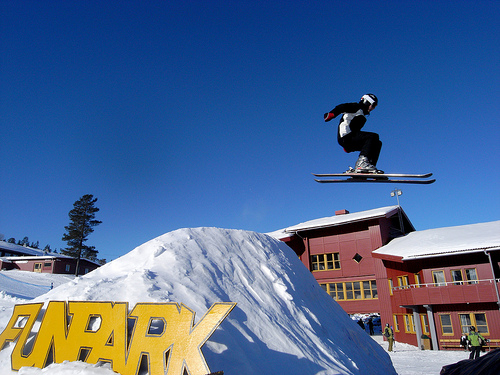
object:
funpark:
[0, 298, 240, 375]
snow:
[185, 238, 244, 287]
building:
[260, 186, 499, 353]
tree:
[59, 195, 104, 276]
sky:
[93, 4, 245, 119]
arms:
[330, 103, 360, 119]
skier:
[323, 90, 386, 177]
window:
[309, 251, 341, 272]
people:
[465, 327, 490, 360]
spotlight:
[388, 191, 397, 199]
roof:
[370, 219, 500, 264]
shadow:
[201, 260, 325, 375]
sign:
[0, 300, 237, 375]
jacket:
[467, 330, 487, 346]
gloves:
[324, 112, 335, 122]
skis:
[313, 172, 435, 179]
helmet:
[359, 93, 379, 107]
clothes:
[338, 130, 383, 167]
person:
[380, 322, 394, 353]